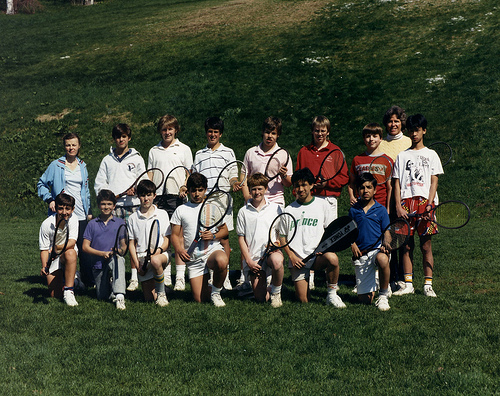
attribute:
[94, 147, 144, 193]
hoodie — white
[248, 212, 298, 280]
tennis racket — black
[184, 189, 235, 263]
tennis racket — black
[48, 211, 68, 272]
tennis racket — black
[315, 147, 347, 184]
tennis racket — black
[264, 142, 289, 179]
tennis racket — black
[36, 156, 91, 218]
jacket — pale blue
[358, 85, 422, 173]
lady — smiling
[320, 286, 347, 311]
shoes — white, tennis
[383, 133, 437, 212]
shirt — red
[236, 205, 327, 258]
racket — tennis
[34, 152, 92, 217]
jacket — light blue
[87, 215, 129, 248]
shirt — purple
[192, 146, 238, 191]
striped shirt — white, polo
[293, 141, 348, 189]
shirt — red, long 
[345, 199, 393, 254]
shirt — blue 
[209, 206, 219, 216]
laces — clear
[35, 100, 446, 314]
team — tennis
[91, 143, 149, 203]
hoodie — white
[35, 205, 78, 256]
shirt — white